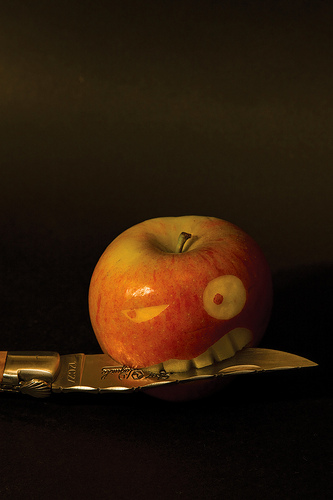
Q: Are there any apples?
A: Yes, there is an apple.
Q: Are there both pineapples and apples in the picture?
A: No, there is an apple but no pineapples.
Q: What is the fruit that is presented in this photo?
A: The fruit is an apple.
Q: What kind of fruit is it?
A: The fruit is an apple.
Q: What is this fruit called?
A: This is an apple.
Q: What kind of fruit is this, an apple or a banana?
A: This is an apple.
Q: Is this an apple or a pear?
A: This is an apple.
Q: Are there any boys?
A: No, there are no boys.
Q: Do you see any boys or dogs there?
A: No, there are no boys or dogs.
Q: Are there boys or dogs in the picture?
A: No, there are no boys or dogs.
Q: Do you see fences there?
A: No, there are no fences.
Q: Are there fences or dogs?
A: No, there are no fences or dogs.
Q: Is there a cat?
A: No, there are no cats.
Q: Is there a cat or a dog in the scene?
A: No, there are no cats or dogs.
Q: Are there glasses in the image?
A: No, there are no glasses.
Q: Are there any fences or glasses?
A: No, there are no glasses or fences.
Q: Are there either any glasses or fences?
A: No, there are no glasses or fences.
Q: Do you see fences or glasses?
A: No, there are no glasses or fences.